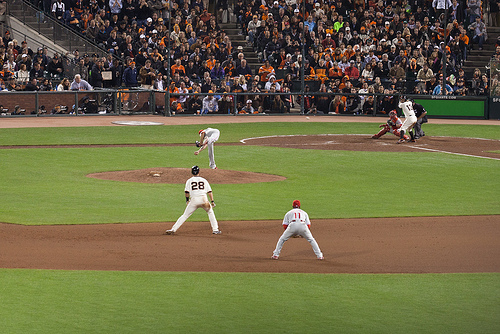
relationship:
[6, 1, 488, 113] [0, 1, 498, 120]
fans sitting in bleachers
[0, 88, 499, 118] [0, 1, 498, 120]
fence in front of bleachers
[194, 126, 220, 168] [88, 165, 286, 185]
pitcher has mound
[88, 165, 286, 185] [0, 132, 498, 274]
mound inside of diamond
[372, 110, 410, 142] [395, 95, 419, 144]
catcher behind players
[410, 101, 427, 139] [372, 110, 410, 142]
umpire behind catcher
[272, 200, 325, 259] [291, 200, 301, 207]
man wearing cap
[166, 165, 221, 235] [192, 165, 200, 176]
man wearing helmet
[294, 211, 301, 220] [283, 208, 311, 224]
number on shirt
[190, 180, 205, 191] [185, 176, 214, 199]
number on shirt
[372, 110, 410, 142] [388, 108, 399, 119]
catcher wearing helmet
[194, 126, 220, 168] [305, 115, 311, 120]
pitcher throwing ball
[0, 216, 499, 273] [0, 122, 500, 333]
dirt lying on field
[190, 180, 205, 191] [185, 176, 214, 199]
number printed on shirt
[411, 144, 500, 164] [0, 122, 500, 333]
line drawn on field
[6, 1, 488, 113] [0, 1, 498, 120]
fans in bleachers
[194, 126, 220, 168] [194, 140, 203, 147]
pitcher has glove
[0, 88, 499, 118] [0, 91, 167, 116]
fence protects dugout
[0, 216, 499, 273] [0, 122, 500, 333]
dirt on field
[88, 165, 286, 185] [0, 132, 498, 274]
mound in diamond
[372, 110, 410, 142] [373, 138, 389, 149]
catcher behind plate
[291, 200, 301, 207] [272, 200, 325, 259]
cap on man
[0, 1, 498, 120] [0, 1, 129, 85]
bleachers have stairs